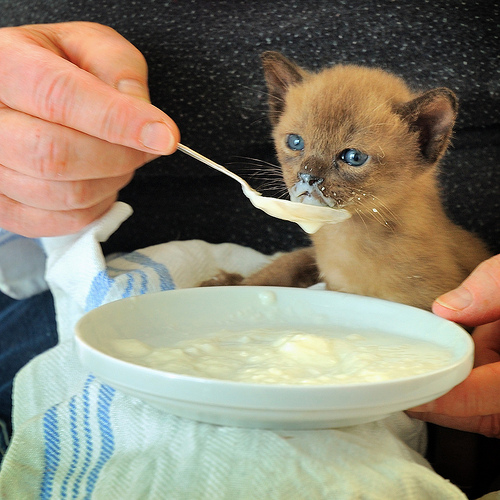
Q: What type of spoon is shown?
A: Plastic.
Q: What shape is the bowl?
A: Round.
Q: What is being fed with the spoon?
A: The kitten.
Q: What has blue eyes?
A: The tan kitten.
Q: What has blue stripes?
A: The white towel.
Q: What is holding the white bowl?
A: The hand.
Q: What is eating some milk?
A: The kitten.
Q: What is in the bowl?
A: Food.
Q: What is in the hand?
A: Spoon.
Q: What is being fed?
A: The kitten.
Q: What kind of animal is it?
A: A kitten.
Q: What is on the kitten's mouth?
A: Kitten formula.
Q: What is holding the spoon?
A: The hand.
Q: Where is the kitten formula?
A: In the saucer.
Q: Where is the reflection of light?
A: In the kitten's eyes.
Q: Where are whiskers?
A: On cat's face.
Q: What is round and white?
A: A bowl.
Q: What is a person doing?
A: Feeding a cat.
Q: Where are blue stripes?
A: On white towel.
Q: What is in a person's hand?
A: A spoon.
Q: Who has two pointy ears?
A: The cat.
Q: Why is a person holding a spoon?
A: To feed the cat.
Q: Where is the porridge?
A: In a bowl.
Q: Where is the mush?
A: Inside bowl.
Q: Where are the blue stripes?
A: On the towel.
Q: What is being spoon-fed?
A: A kitten.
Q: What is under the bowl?
A: Kitchen towel.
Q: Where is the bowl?
A: On a towel on a person's lap.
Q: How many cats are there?
A: One.